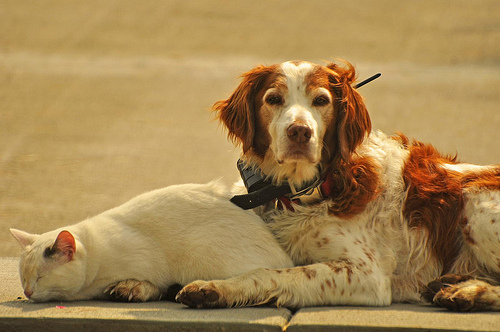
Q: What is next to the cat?
A: A dog.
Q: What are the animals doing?
A: They are sitting together.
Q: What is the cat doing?
A: Laying on the dogs paw.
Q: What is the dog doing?
A: Laying on the cat.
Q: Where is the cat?
A: Sleeping on the dog's paw.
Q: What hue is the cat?
A: White.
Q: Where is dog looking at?
A: Camera.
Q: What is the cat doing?
A: Sleeping.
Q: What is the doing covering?
A: The cat.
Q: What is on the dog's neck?
A: Collar.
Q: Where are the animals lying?
A: Sidewalk.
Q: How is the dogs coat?
A: Clean and furry.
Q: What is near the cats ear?
A: Black mark.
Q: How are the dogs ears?
A: Long.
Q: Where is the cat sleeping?
A: On the dogs hand.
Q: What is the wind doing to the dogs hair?
A: Ruffling it.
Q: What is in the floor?
A: Dogs.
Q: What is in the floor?
A: Brown dog.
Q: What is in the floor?
A: Red collar.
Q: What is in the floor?
A: Cat.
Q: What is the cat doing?
A: Sleepign.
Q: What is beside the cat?
A: Dog.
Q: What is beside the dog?
A: Cat.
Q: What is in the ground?
A: Cat.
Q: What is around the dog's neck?
A: Collar.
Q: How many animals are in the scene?
A: Two.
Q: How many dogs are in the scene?
A: One.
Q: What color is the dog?
A: Brown and white.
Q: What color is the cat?
A: White.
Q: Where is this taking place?
A: Outside, during the daytime.